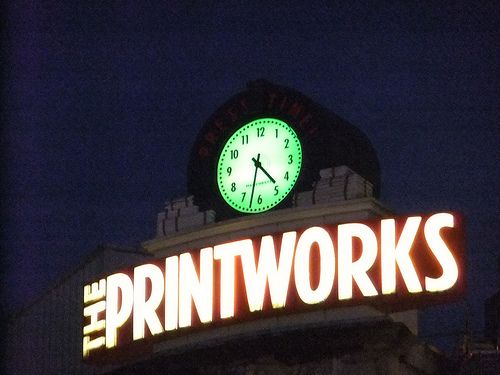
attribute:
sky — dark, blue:
[2, 1, 498, 372]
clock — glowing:
[213, 117, 308, 213]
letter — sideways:
[80, 332, 105, 359]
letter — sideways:
[80, 297, 107, 336]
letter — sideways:
[78, 275, 106, 306]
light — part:
[407, 194, 475, 319]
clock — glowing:
[218, 112, 304, 217]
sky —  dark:
[16, 14, 463, 266]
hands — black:
[248, 153, 275, 204]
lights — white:
[60, 216, 455, 370]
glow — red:
[54, 206, 459, 319]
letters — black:
[238, 168, 283, 190]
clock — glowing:
[202, 110, 319, 218]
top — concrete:
[135, 76, 395, 254]